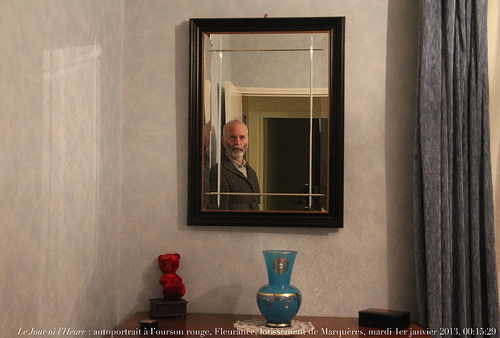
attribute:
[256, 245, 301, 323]
vase — blue, silver, red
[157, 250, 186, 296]
teddy bear — red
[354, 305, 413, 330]
box — black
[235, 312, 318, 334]
white doily — beneath a vase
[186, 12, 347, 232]
black/framed mirror — on a wall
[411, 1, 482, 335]
blue-gray drapes — thick, on a window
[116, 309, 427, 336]
small/brown table — against the wall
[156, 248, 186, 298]
red/stuffed animal — on the table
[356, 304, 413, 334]
jewelry box — small, black, on the table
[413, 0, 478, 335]
grey/creased curtain — bunched to one side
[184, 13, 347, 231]
black mirror — hanging on the wall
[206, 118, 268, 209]
man's reflection — of a man in the mirror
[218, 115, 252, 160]
bald man — with a white beard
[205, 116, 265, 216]
man — wearing a brown striped jacket, brown and white beard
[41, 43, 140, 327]
light glimmer — on the wall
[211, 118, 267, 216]
man — looking at himself in the mirror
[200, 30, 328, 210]
mirror — on the wall, wooden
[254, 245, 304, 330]
vase — blue, light blue, on the table, on a table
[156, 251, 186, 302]
teddy bear — on a table, red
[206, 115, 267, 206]
man — wearing a jacket, with a gray beard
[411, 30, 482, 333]
blue curtains — beside a mirror on the wall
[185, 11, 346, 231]
mirror — frame, black, framed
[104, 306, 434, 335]
stand — wooden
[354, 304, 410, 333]
box — wooden, black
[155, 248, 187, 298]
bear — teddy, small, red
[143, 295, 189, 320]
box — brown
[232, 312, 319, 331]
doily — white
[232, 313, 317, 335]
doily — white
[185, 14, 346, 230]
frame — brown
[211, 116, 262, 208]
reflection — person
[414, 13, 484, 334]
covering — gray, window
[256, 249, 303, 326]
vase — blue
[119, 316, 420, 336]
table — wooden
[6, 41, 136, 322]
wall — white colored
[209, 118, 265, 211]
reflection — man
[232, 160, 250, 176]
shirt — tan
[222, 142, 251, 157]
beard — gray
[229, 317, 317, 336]
doilie — lace